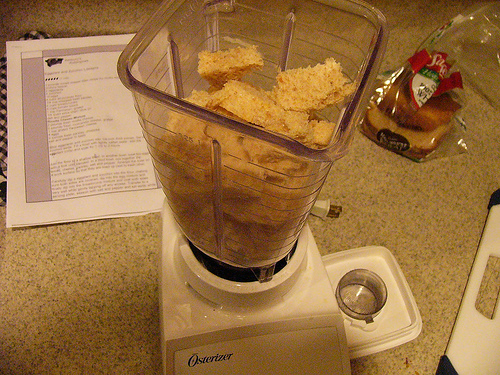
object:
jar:
[115, 0, 387, 286]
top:
[324, 242, 424, 361]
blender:
[111, 0, 400, 373]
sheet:
[4, 35, 176, 231]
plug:
[310, 196, 344, 221]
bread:
[152, 37, 354, 268]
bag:
[361, 0, 498, 168]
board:
[437, 187, 500, 373]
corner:
[487, 186, 499, 210]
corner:
[432, 356, 457, 374]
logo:
[188, 350, 233, 369]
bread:
[360, 62, 461, 161]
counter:
[2, 0, 499, 374]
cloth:
[0, 32, 14, 203]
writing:
[409, 53, 457, 109]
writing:
[377, 129, 410, 152]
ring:
[184, 240, 306, 280]